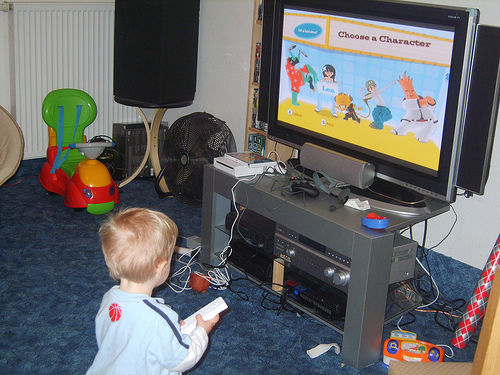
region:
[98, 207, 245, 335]
this is a little kid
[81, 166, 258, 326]
this is a little boy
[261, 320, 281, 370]
this is a plush carpet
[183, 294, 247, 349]
this is a wii remote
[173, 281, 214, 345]
the wii is white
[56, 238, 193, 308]
this is a neck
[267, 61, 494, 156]
the tv is on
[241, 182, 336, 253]
this is a stand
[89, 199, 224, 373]
A small boy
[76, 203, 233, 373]
A boy holding a wii controller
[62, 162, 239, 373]
A boy facing the television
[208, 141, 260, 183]
A white wii console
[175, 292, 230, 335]
A white wii controller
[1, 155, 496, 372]
Blue flooring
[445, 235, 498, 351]
A silver and red roll of wrapping paper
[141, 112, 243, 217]
A round black fan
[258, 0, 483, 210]
A television turned on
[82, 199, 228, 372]
Boy wearing a blue shirt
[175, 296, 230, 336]
Game control in the boy's hand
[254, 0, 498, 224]
TV on the stand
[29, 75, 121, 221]
Child's ride on toy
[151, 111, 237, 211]
Fan on the floor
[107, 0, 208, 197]
Speaker on a stand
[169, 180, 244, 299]
Cords hanging from stand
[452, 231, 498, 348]
Wrapping paper leaning on wall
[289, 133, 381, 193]
Speaker in front of tv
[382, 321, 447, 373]
Toy on the floor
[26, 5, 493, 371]
A child is playing a videogame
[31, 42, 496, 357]
The child is entertaining himself well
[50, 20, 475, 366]
A child is in a living room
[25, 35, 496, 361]
A child is using a television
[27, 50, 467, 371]
A child is using a game controller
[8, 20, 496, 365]
A child is having a great time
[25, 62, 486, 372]
A child is sitting on the carpet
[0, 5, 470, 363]
A child is watching the TV screen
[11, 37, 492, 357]
A child is enjoying a present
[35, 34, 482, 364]
A child is enjoying the day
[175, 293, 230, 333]
white wii control in a young boy's hand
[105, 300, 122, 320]
red graphic on the back of a light blue shirt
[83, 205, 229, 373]
little boy holding Nintendo wii remote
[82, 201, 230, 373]
little boy playing Nintendo Wii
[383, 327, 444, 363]
orange toy on a blue carpet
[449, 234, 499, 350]
roll of a red and silver paper wrapper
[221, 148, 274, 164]
Nintendo Wii game case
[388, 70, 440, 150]
character of a game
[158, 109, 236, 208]
black round fan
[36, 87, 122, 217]
colorful toy car on a blue carpet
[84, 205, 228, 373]
a small child with a remote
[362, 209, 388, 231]
a blue and red button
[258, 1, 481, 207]
a black and silver TV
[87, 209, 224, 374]
child is holding a remote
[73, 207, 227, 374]
kid is watching tv